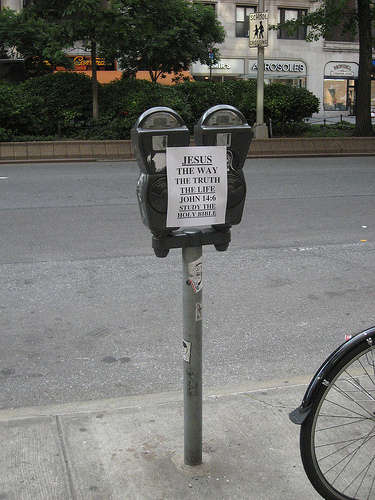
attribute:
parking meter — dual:
[132, 101, 252, 462]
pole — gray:
[182, 245, 204, 470]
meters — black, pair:
[131, 106, 250, 259]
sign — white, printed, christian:
[164, 145, 229, 229]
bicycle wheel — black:
[289, 324, 374, 499]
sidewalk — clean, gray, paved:
[0, 380, 374, 497]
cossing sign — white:
[248, 11, 271, 51]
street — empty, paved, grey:
[0, 157, 372, 407]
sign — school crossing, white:
[247, 8, 270, 48]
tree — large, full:
[0, 1, 221, 121]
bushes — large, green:
[0, 75, 323, 140]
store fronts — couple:
[0, 1, 375, 116]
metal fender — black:
[286, 323, 373, 426]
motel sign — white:
[323, 59, 362, 80]